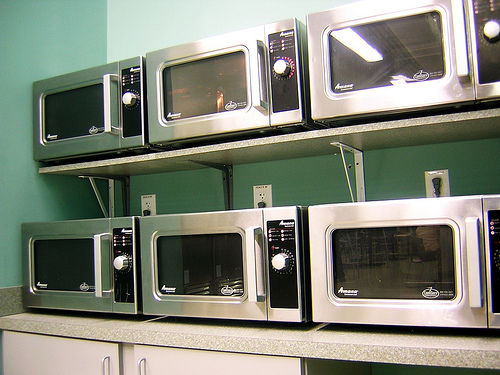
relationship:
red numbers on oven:
[259, 50, 312, 85] [136, 22, 299, 141]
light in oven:
[160, 50, 261, 140] [138, 10, 312, 154]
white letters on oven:
[160, 104, 198, 123] [141, 19, 313, 148]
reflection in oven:
[332, 223, 457, 294] [302, 180, 498, 343]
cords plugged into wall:
[111, 153, 474, 207] [4, 5, 495, 352]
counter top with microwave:
[14, 305, 244, 355] [12, 210, 307, 320]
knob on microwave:
[270, 246, 294, 277] [135, 204, 304, 327]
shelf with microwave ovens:
[50, 122, 334, 196] [25, 13, 322, 168]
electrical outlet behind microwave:
[237, 175, 277, 209] [127, 200, 309, 335]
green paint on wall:
[8, 170, 52, 210] [0, 152, 62, 212]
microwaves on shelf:
[6, 0, 497, 181] [34, 95, 498, 190]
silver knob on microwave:
[265, 234, 294, 275] [138, 197, 304, 344]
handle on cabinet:
[93, 351, 119, 371] [5, 327, 324, 371]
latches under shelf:
[327, 133, 377, 214] [34, 95, 498, 190]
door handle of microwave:
[243, 28, 267, 120] [141, 11, 312, 162]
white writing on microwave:
[335, 281, 365, 299] [300, 180, 498, 343]